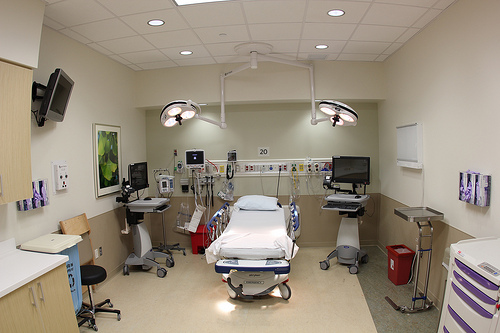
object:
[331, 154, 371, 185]
computer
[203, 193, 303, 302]
bed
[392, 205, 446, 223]
silver tray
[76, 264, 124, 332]
stool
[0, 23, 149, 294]
wall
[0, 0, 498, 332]
hospital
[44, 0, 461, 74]
ceiling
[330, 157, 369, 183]
monitor screen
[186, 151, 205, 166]
monitor screen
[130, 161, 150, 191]
monitor screen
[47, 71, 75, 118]
monitor screen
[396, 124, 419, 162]
screen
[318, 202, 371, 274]
stand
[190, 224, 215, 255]
trash can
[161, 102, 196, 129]
lamps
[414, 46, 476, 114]
black shoes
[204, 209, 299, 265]
white sheet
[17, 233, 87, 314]
bin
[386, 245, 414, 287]
can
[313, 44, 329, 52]
bulbs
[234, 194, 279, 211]
pillow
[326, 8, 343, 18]
lighting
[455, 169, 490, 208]
boxes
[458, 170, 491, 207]
gloves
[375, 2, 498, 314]
wall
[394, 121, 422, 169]
box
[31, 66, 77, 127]
tv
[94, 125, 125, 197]
picture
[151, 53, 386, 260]
wall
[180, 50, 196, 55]
lights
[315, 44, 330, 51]
lights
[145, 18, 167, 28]
lights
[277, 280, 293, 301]
wheel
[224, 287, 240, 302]
wheel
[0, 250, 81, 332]
cabinet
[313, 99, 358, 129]
light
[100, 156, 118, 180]
leaf